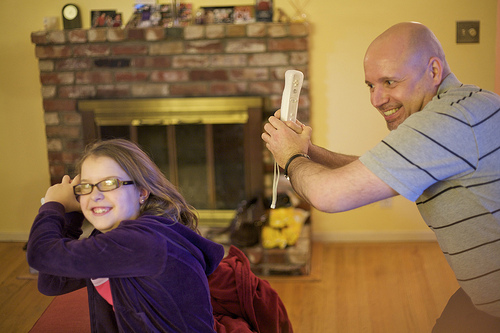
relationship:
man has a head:
[261, 21, 500, 332] [363, 23, 456, 131]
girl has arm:
[28, 138, 239, 332] [23, 170, 167, 280]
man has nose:
[261, 21, 500, 332] [371, 87, 390, 109]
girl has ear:
[28, 138, 239, 332] [138, 182, 151, 205]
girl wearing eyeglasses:
[28, 138, 239, 332] [71, 177, 143, 199]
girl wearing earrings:
[28, 138, 239, 332] [140, 198, 146, 205]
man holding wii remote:
[261, 21, 500, 332] [269, 68, 305, 211]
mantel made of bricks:
[25, 18, 316, 68] [33, 22, 312, 56]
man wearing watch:
[261, 21, 500, 332] [284, 149, 310, 182]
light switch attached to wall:
[455, 19, 481, 45] [1, 0, 499, 228]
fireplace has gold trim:
[28, 23, 311, 272] [78, 96, 265, 233]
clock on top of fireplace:
[62, 1, 83, 33] [28, 23, 311, 272]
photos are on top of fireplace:
[86, 0, 279, 28] [28, 23, 311, 272]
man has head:
[261, 21, 500, 332] [363, 23, 456, 131]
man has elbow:
[261, 21, 500, 332] [299, 164, 346, 220]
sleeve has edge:
[359, 101, 479, 204] [360, 152, 420, 205]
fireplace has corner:
[28, 23, 311, 272] [289, 17, 314, 45]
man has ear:
[261, 21, 500, 332] [429, 54, 444, 88]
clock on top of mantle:
[62, 1, 83, 33] [25, 18, 316, 68]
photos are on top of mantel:
[86, 0, 279, 28] [25, 18, 316, 68]